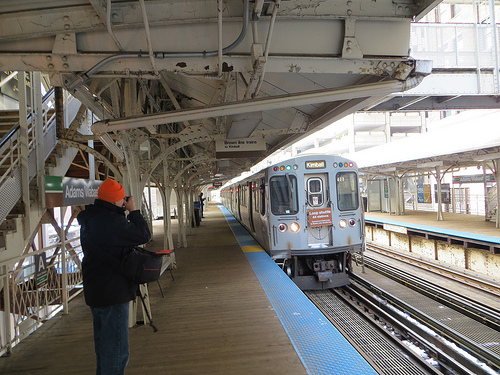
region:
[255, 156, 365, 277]
the front of a train.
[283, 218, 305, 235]
a headlight on a train.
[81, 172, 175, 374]
a person wearing a red beanie.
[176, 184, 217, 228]
people waiting for a train.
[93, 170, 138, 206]
a man wearing a red beanie.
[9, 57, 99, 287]
a set of stairs leading up to a platform.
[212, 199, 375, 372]
a blue line near a train station.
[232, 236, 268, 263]
a section of yellow paint.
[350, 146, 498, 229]
a structure near tracks.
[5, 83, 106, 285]
a set of stairs.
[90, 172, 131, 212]
the head of a person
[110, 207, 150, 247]
the arm of a person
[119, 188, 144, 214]
the hand of a person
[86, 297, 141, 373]
a pair of blue jeans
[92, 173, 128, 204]
an orange stocking cap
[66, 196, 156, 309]
a black coat on the person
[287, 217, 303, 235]
a head light on the train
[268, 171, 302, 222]
a windshield on the train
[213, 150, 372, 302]
a train on the tracks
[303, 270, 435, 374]
tracks in front of the train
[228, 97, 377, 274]
the train is blue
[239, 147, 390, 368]
the train is blue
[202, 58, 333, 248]
the train is blue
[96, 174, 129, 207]
an orange hat on a man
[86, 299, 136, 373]
jeans on a man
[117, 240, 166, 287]
a black bag carried by a man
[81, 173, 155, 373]
a man taking a picture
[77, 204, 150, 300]
a black coat on a man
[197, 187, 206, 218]
a man on the other end of the platform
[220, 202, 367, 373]
the blue platform edge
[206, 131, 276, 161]
a white sign on a platform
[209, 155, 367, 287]
a grey train pulling into the station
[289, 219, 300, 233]
a round headlight on a train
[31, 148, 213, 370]
man taking a picture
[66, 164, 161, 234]
bright orange hat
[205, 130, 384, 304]
grey train on tracks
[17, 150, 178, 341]
man wearing a black jacket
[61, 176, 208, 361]
man wearing blue jeans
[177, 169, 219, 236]
a person standing at a station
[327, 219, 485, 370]
metal train tracks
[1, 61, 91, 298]
white metal staircase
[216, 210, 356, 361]
aqua colored strip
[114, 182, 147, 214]
black camera up to a mans face